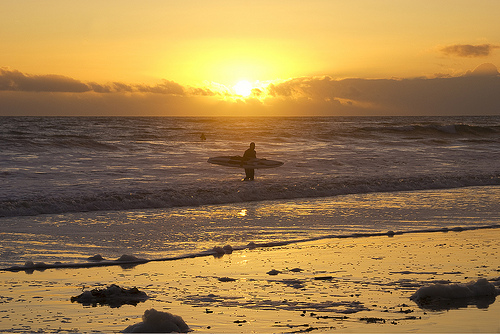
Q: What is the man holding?
A: Surfboard.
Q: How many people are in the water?
A: One.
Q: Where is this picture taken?
A: Beach.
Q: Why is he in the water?
A: Surfing.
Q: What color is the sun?
A: Yellow.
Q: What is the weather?
A: Partly cloudy.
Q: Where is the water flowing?
A: Into the ocean.